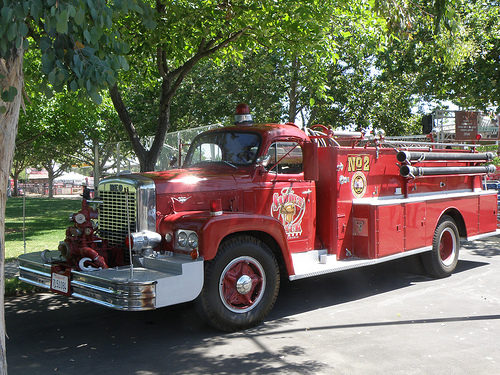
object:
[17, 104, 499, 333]
engine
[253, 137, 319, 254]
door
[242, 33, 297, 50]
branches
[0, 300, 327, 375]
shadow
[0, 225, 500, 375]
road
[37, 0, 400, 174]
tree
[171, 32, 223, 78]
branch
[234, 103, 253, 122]
light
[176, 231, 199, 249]
headlight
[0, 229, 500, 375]
street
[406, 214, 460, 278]
tire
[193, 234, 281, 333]
tire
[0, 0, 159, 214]
tree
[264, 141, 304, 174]
window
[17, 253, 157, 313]
bumper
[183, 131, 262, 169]
windshield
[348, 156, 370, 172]
no2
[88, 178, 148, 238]
grill